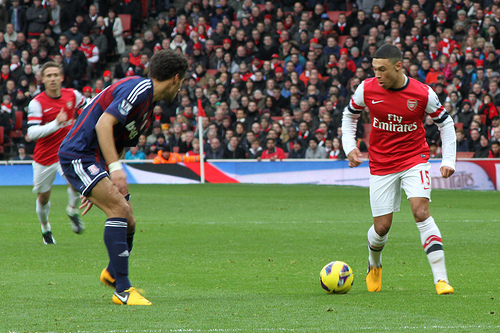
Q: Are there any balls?
A: Yes, there is a ball.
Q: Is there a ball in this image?
A: Yes, there is a ball.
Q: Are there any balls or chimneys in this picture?
A: Yes, there is a ball.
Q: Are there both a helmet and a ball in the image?
A: No, there is a ball but no helmets.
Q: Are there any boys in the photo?
A: No, there are no boys.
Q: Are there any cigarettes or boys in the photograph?
A: No, there are no boys or cigarettes.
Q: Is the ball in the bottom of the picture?
A: Yes, the ball is in the bottom of the image.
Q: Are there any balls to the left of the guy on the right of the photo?
A: Yes, there is a ball to the left of the guy.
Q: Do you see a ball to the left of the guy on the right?
A: Yes, there is a ball to the left of the guy.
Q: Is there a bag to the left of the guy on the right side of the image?
A: No, there is a ball to the left of the guy.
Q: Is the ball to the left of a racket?
A: No, the ball is to the left of a guy.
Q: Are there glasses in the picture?
A: No, there are no glasses.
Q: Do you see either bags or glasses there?
A: No, there are no glasses or bags.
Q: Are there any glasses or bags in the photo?
A: No, there are no glasses or bags.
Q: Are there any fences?
A: No, there are no fences.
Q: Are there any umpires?
A: No, there are no umpires.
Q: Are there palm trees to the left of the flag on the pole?
A: No, there is a guy to the left of the flag.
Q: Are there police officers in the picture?
A: No, there are no police officers.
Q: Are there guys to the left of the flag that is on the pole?
A: Yes, there is a guy to the left of the flag.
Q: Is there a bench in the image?
A: No, there are no benches.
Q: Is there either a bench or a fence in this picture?
A: No, there are no benches or fences.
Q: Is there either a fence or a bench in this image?
A: No, there are no benches or fences.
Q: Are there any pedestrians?
A: No, there are no pedestrians.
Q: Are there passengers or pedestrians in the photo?
A: No, there are no pedestrians or passengers.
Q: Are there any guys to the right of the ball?
A: Yes, there is a guy to the right of the ball.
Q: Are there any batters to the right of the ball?
A: No, there is a guy to the right of the ball.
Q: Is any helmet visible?
A: No, there are no helmets.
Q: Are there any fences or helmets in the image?
A: No, there are no helmets or fences.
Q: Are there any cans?
A: No, there are no cans.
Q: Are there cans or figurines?
A: No, there are no cans or figurines.